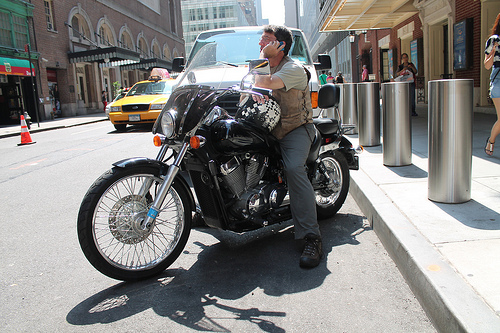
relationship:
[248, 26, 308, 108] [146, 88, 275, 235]
man on motorcycle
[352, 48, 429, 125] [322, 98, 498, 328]
people on sidewalk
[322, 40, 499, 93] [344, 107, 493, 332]
people on sidewalk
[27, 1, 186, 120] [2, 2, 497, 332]
building in city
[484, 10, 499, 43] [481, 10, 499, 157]
hair on woman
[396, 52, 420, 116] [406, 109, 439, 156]
people on sidewalk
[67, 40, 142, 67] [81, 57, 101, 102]
awning on doorway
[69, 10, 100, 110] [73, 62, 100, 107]
arch over doorway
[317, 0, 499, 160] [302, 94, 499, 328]
people on sidewalk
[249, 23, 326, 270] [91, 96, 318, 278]
man on a motorcycle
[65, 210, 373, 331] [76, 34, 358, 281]
shadow of a motorcycle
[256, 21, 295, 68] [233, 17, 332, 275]
head of a man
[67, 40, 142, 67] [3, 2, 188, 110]
awning over a building